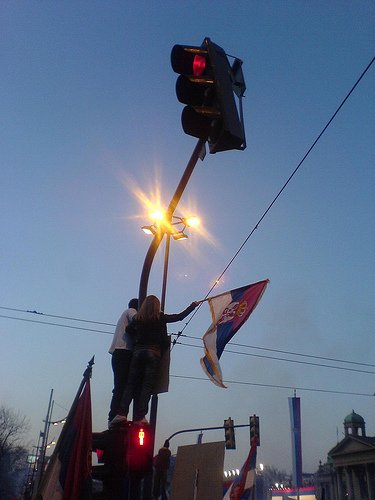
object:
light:
[191, 55, 204, 76]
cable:
[233, 55, 374, 260]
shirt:
[123, 303, 194, 348]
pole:
[161, 236, 171, 310]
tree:
[0, 382, 27, 496]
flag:
[197, 281, 268, 386]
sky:
[0, 1, 159, 173]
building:
[309, 410, 370, 498]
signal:
[169, 37, 251, 151]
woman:
[125, 294, 200, 429]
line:
[34, 311, 109, 325]